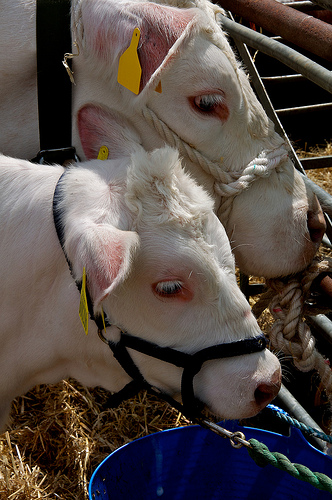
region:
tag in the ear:
[110, 24, 154, 100]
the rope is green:
[247, 437, 330, 495]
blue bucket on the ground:
[65, 413, 331, 496]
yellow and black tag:
[71, 271, 96, 340]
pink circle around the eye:
[153, 276, 193, 304]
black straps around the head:
[39, 160, 298, 436]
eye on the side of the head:
[145, 274, 207, 309]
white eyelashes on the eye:
[155, 280, 182, 290]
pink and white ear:
[71, 99, 154, 161]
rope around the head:
[101, 68, 326, 284]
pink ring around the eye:
[149, 273, 198, 307]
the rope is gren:
[249, 435, 329, 483]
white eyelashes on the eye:
[152, 278, 190, 300]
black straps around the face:
[81, 299, 293, 441]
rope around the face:
[142, 90, 326, 301]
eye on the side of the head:
[187, 88, 233, 129]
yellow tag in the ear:
[117, 30, 147, 94]